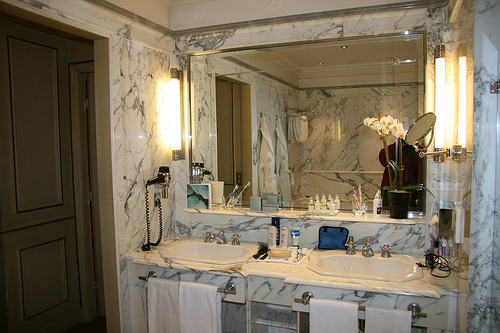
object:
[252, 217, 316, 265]
containers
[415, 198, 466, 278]
items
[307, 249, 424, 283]
sink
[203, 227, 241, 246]
faucet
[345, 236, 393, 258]
faucet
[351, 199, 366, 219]
glass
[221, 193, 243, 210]
glass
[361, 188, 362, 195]
glass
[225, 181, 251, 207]
toothbrush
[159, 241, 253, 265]
sink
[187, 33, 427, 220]
mirror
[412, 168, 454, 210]
ground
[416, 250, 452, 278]
blackcord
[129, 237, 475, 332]
counter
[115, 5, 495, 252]
wall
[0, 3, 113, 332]
doorway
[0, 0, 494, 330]
bathroom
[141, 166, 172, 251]
hairdryer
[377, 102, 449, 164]
ground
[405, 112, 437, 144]
mirror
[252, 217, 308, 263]
toiletries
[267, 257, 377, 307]
marble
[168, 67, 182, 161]
light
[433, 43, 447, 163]
light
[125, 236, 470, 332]
sink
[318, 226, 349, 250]
blue bag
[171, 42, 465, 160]
lights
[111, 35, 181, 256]
wall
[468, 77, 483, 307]
wall